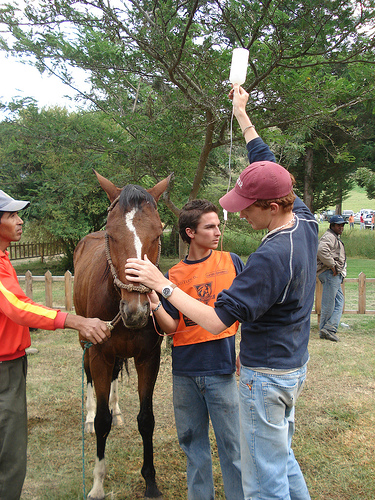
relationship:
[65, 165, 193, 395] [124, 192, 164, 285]
horse with white stripe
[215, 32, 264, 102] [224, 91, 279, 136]
white bottle held by the hand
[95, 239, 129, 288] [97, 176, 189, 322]
rope on horse's head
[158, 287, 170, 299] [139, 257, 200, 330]
black faced wrist watch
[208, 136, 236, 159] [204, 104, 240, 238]
white drip line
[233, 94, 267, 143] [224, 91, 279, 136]
metallic bracelet wrist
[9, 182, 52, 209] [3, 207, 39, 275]
grey cap on the head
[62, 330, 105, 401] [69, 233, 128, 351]
string hanging from horse's side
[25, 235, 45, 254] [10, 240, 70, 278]
part of a fence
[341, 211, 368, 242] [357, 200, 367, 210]
people in background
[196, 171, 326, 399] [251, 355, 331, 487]
man wearing jeans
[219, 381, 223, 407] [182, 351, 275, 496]
blue jean pants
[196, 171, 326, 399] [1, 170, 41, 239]
man wearing grey hat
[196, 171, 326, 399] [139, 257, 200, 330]
man wearing watch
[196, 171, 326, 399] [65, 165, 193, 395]
man touching horse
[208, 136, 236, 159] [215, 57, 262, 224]
white bottle tube attached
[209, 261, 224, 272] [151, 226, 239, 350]
bright orange vest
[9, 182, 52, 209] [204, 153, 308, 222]
grey colored hat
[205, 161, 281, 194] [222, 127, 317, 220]
maroon ball cap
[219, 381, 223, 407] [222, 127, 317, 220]
blue ball cap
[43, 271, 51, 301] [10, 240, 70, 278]
brown wooden fence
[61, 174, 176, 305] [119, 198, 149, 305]
brown horse with white markings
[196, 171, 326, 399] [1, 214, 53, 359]
man wearing red windbreaker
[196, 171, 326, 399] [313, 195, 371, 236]
man wearing blue cap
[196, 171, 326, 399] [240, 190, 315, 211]
man with red hair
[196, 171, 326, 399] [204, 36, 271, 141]
man holding iv bottle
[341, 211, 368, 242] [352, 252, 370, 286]
people standing in grass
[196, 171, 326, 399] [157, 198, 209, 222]
man with short brown hair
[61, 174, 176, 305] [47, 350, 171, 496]
brown horse with white and black legs